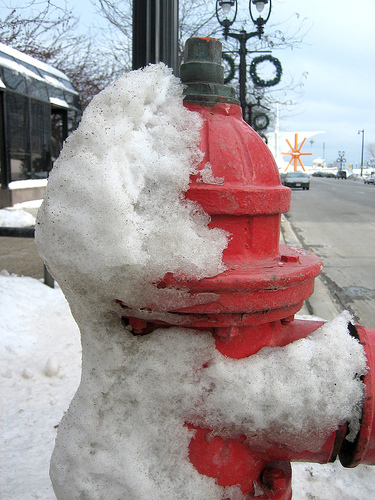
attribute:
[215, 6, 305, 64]
streetlights — gas lamps, fashioned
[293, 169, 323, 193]
car — driving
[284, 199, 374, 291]
street — city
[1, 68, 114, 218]
building — business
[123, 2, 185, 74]
pole — utility, metal, green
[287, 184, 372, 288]
streets — clear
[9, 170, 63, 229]
sidewalks — snowy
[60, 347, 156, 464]
snow — white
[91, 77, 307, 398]
hydrant — red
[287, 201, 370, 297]
street — grey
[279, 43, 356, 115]
clouds — white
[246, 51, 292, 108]
wreath — hanging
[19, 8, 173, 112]
trees — behind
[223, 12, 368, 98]
sky — above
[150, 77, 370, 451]
hydrant — red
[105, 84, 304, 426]
hydrant — white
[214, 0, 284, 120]
light — street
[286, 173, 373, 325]
road — clear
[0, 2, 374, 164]
sky — clear